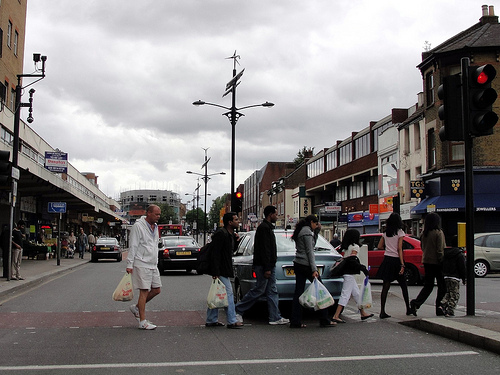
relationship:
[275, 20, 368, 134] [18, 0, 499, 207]
cloud in sky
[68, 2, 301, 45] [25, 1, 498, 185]
cloud in sky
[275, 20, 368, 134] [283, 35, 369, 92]
cloud in blue sky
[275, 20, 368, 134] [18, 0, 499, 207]
cloud in blue sky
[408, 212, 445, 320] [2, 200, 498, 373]
people walking across street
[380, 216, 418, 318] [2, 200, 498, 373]
people walking across street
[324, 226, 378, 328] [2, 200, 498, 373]
people walking across street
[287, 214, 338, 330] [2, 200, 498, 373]
lady walking across street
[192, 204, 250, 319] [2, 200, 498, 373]
guy walking across street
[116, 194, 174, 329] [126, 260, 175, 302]
guy in shorts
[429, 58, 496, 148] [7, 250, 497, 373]
traffic light on street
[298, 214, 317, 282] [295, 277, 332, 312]
lady holding bags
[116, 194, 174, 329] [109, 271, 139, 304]
guy holding bag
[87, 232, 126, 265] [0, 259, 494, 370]
car on side of road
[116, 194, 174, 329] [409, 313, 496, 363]
guy on sidewalk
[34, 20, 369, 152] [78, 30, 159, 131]
cloud in sky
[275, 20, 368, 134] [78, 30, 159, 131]
cloud in sky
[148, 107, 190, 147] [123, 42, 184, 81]
clouds in sky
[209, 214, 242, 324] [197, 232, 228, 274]
boy holding bag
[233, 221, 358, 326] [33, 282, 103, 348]
car driving on street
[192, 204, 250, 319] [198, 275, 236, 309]
guy holding plastic bag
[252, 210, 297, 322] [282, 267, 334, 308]
guy holding plastic bag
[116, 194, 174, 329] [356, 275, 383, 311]
guy holding plastic bag